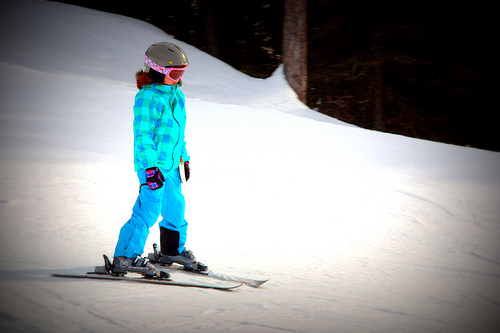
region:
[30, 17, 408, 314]
a girl skiing down a slope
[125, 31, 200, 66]
a gray ski helmet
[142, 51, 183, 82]
a pair of pink ski goggles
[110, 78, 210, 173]
a striped blue ski jacket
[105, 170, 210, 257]
a pair of blue ski pants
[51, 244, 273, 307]
a pair of white snow skis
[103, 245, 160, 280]
a gray ski boot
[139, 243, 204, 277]
a gray ski boot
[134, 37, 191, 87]
the head of a girl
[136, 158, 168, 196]
colorful ski gloves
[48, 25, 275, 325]
this is a child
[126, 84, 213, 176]
kid wearing a blue jacket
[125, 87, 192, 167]
kids jacket is plaid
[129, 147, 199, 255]
kid wearing blue pants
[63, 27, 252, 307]
a kid standing on skis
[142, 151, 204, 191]
kid wearing black gloves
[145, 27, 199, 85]
kid wearing a helmet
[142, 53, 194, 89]
kid wearing pink goggles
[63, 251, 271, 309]
this is a set of skis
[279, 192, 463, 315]
ski tracks in snow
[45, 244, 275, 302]
Child on skis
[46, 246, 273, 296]
Child is on skis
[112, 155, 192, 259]
Child wearing pants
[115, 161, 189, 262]
Child is wearing pants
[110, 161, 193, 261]
Child wearing blue pants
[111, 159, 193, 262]
Child is wearing blue pants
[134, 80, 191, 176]
Child is wearing a jacket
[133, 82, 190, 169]
Child wearing a jacket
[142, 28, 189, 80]
Child wearing a gray helmet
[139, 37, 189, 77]
Child is wearing a gray helmet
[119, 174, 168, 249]
leg of a person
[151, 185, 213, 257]
leg of a person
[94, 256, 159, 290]
feet of a person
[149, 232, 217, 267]
feet of a person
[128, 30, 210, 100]
head of a person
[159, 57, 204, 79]
goggle of a person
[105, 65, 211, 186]
body of a person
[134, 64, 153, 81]
hair of a person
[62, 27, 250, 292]
person on a pair of ski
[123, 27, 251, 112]
person wearing a helmet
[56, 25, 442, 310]
a young girl skiing down a slope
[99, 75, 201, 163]
a blue ski jacket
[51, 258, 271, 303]
a pair of white skis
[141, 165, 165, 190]
a black ski glove